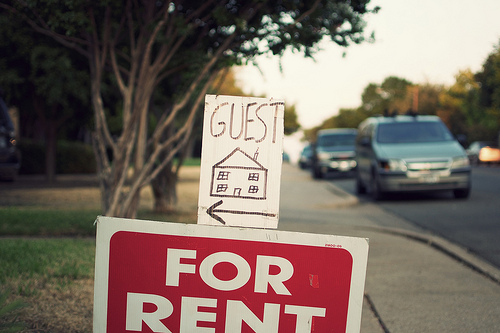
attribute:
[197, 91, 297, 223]
sign — rectangular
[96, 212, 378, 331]
rent sign — red, white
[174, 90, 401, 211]
sign — hand written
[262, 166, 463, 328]
sidewalk — gray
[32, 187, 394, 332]
sign — red, white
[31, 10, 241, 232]
trees — green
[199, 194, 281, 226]
arrow — hand drawn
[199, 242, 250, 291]
o — letter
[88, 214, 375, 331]
sign — red, white, plastic